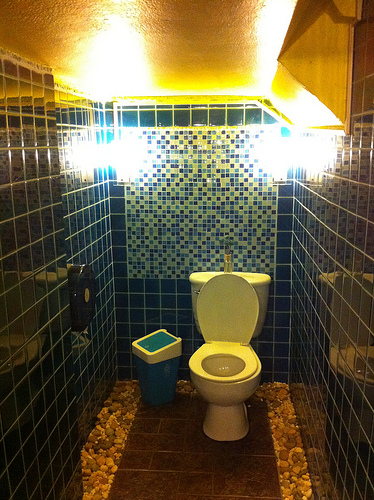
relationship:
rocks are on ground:
[72, 377, 142, 492] [71, 380, 309, 496]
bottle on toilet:
[217, 240, 240, 276] [180, 262, 274, 446]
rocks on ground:
[72, 377, 142, 492] [71, 380, 309, 496]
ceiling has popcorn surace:
[4, 6, 353, 130] [174, 5, 249, 59]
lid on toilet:
[193, 272, 263, 347] [180, 262, 274, 446]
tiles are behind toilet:
[119, 126, 275, 277] [180, 262, 274, 446]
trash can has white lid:
[125, 321, 189, 415] [128, 326, 181, 364]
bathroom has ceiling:
[1, 6, 373, 498] [4, 6, 353, 130]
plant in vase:
[213, 234, 237, 252] [217, 251, 246, 276]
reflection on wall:
[313, 260, 373, 442] [297, 132, 370, 498]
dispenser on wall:
[64, 253, 96, 348] [50, 87, 112, 443]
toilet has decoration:
[180, 262, 274, 446] [193, 379, 244, 415]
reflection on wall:
[296, 135, 344, 182] [297, 132, 370, 498]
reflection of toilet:
[313, 260, 373, 442] [180, 262, 274, 446]